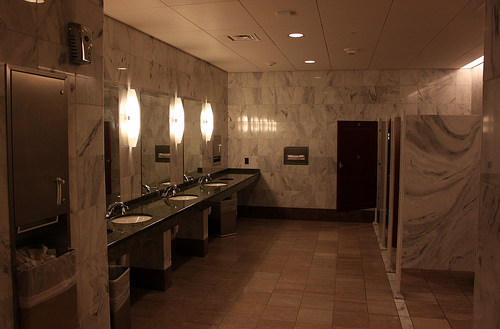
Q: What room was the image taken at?
A: It was taken at the bathroom.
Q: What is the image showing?
A: It is showing a bathroom.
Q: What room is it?
A: It is a bathroom.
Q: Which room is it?
A: It is a bathroom.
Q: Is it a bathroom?
A: Yes, it is a bathroom.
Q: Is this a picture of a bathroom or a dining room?
A: It is showing a bathroom.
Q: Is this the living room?
A: No, it is the bathroom.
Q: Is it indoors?
A: Yes, it is indoors.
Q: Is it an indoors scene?
A: Yes, it is indoors.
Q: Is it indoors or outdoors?
A: It is indoors.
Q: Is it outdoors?
A: No, it is indoors.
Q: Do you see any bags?
A: Yes, there is a bag.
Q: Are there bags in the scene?
A: Yes, there is a bag.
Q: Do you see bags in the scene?
A: Yes, there is a bag.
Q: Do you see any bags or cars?
A: Yes, there is a bag.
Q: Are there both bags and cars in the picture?
A: No, there is a bag but no cars.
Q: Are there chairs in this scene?
A: No, there are no chairs.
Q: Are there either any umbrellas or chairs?
A: No, there are no chairs or umbrellas.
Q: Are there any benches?
A: No, there are no benches.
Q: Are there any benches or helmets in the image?
A: No, there are no benches or helmets.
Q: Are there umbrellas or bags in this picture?
A: Yes, there is a bag.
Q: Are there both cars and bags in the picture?
A: No, there is a bag but no cars.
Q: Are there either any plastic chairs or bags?
A: Yes, there is a plastic bag.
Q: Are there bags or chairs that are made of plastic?
A: Yes, the bag is made of plastic.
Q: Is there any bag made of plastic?
A: Yes, there is a bag that is made of plastic.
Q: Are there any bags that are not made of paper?
A: Yes, there is a bag that is made of plastic.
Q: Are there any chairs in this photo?
A: No, there are no chairs.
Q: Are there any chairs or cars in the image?
A: No, there are no chairs or cars.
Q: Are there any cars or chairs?
A: No, there are no chairs or cars.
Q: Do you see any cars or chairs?
A: No, there are no chairs or cars.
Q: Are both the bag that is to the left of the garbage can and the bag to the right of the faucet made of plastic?
A: Yes, both the bag and the bag are made of plastic.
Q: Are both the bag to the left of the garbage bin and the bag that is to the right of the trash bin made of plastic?
A: Yes, both the bag and the bag are made of plastic.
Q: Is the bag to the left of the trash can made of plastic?
A: Yes, the bag is made of plastic.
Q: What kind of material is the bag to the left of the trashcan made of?
A: The bag is made of plastic.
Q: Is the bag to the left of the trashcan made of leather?
A: No, the bag is made of plastic.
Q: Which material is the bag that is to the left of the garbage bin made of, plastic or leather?
A: The bag is made of plastic.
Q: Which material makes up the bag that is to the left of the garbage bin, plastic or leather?
A: The bag is made of plastic.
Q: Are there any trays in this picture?
A: No, there are no trays.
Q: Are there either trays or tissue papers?
A: No, there are no trays or tissue papers.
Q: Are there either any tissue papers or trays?
A: No, there are no trays or tissue papers.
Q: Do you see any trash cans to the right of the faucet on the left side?
A: Yes, there is a trash can to the right of the faucet.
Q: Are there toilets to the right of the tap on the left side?
A: No, there is a trash can to the right of the tap.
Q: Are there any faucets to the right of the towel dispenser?
A: Yes, there is a faucet to the right of the towel dispenser.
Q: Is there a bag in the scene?
A: Yes, there is a bag.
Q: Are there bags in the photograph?
A: Yes, there is a bag.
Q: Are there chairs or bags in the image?
A: Yes, there is a bag.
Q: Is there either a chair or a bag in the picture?
A: Yes, there is a bag.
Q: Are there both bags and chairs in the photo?
A: No, there is a bag but no chairs.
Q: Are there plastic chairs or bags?
A: Yes, there is a plastic bag.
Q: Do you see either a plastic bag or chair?
A: Yes, there is a plastic bag.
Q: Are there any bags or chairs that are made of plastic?
A: Yes, the bag is made of plastic.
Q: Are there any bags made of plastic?
A: Yes, there is a bag that is made of plastic.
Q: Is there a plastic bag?
A: Yes, there is a bag that is made of plastic.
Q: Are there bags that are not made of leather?
A: Yes, there is a bag that is made of plastic.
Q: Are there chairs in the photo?
A: No, there are no chairs.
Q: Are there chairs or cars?
A: No, there are no chairs or cars.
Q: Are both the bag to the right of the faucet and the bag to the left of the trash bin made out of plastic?
A: Yes, both the bag and the bag are made of plastic.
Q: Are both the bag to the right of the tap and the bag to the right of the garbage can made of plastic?
A: Yes, both the bag and the bag are made of plastic.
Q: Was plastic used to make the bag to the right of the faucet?
A: Yes, the bag is made of plastic.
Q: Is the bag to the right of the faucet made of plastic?
A: Yes, the bag is made of plastic.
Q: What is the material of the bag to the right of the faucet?
A: The bag is made of plastic.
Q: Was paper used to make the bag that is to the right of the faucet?
A: No, the bag is made of plastic.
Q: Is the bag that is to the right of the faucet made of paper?
A: No, the bag is made of plastic.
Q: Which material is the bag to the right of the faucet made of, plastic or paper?
A: The bag is made of plastic.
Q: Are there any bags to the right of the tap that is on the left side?
A: Yes, there is a bag to the right of the faucet.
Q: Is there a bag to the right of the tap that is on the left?
A: Yes, there is a bag to the right of the faucet.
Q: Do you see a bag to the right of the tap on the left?
A: Yes, there is a bag to the right of the faucet.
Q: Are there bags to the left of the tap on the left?
A: No, the bag is to the right of the tap.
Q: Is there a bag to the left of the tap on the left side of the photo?
A: No, the bag is to the right of the tap.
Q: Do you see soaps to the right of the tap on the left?
A: No, there is a bag to the right of the faucet.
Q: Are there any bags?
A: Yes, there is a bag.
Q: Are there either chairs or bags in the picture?
A: Yes, there is a bag.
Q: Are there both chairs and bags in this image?
A: No, there is a bag but no chairs.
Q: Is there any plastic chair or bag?
A: Yes, there is a plastic bag.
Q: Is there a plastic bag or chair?
A: Yes, there is a plastic bag.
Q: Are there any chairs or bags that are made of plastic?
A: Yes, the bag is made of plastic.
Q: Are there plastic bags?
A: Yes, there is a bag that is made of plastic.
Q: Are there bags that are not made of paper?
A: Yes, there is a bag that is made of plastic.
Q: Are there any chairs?
A: No, there are no chairs.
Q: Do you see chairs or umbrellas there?
A: No, there are no chairs or umbrellas.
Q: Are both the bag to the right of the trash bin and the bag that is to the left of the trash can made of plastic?
A: Yes, both the bag and the bag are made of plastic.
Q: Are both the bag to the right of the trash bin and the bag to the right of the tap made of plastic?
A: Yes, both the bag and the bag are made of plastic.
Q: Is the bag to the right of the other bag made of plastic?
A: Yes, the bag is made of plastic.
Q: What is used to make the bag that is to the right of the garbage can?
A: The bag is made of plastic.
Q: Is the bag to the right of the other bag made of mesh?
A: No, the bag is made of plastic.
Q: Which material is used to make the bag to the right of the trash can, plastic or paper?
A: The bag is made of plastic.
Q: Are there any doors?
A: Yes, there is a door.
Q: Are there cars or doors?
A: Yes, there is a door.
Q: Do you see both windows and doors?
A: No, there is a door but no windows.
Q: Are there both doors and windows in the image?
A: No, there is a door but no windows.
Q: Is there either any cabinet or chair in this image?
A: No, there are no chairs or cabinets.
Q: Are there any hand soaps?
A: No, there are no hand soaps.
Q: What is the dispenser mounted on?
A: The dispenser is mounted on the wall.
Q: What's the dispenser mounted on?
A: The dispenser is mounted on the wall.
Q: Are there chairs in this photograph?
A: No, there are no chairs.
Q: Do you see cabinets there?
A: No, there are no cabinets.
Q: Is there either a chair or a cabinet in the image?
A: No, there are no cabinets or chairs.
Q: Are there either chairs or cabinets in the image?
A: No, there are no cabinets or chairs.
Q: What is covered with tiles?
A: The floor is covered with tiles.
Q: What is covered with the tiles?
A: The floor is covered with tiles.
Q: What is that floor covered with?
A: The floor is covered with tiles.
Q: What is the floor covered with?
A: The floor is covered with tiles.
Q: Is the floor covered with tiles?
A: Yes, the floor is covered with tiles.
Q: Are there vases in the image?
A: No, there are no vases.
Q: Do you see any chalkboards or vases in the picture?
A: No, there are no vases or chalkboards.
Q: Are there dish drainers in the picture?
A: No, there are no dish drainers.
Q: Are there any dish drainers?
A: No, there are no dish drainers.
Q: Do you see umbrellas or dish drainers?
A: No, there are no dish drainers or umbrellas.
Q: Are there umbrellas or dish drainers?
A: No, there are no dish drainers or umbrellas.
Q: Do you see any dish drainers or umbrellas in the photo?
A: No, there are no dish drainers or umbrellas.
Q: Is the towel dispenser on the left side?
A: Yes, the towel dispenser is on the left of the image.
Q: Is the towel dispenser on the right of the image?
A: No, the towel dispenser is on the left of the image.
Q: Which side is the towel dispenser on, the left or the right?
A: The towel dispenser is on the left of the image.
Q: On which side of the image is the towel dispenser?
A: The towel dispenser is on the left of the image.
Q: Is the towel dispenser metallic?
A: Yes, the towel dispenser is metallic.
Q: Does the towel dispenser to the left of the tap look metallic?
A: Yes, the towel dispenser is metallic.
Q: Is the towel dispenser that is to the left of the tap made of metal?
A: Yes, the towel dispenser is made of metal.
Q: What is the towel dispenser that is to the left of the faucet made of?
A: The towel dispenser is made of metal.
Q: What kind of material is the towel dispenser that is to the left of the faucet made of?
A: The towel dispenser is made of metal.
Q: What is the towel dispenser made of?
A: The towel dispenser is made of metal.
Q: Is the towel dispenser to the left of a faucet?
A: Yes, the towel dispenser is to the left of a faucet.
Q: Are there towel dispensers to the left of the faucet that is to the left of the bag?
A: Yes, there is a towel dispenser to the left of the faucet.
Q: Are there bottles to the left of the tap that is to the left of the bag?
A: No, there is a towel dispenser to the left of the tap.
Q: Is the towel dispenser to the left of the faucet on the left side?
A: Yes, the towel dispenser is to the left of the faucet.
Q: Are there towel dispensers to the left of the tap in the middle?
A: Yes, there is a towel dispenser to the left of the tap.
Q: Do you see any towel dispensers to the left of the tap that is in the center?
A: Yes, there is a towel dispenser to the left of the tap.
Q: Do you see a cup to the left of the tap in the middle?
A: No, there is a towel dispenser to the left of the tap.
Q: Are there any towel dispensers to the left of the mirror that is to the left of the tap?
A: Yes, there is a towel dispenser to the left of the mirror.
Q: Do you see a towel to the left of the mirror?
A: No, there is a towel dispenser to the left of the mirror.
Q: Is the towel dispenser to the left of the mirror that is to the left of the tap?
A: Yes, the towel dispenser is to the left of the mirror.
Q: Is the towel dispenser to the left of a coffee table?
A: No, the towel dispenser is to the left of the mirror.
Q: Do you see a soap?
A: No, there are no soaps.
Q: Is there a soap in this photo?
A: No, there are no soaps.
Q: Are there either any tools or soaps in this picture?
A: No, there are no soaps or tools.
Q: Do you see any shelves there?
A: No, there are no shelves.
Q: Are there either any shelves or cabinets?
A: No, there are no shelves or cabinets.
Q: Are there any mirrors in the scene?
A: Yes, there is a mirror.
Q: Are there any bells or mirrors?
A: Yes, there is a mirror.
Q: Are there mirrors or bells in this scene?
A: Yes, there is a mirror.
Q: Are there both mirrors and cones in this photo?
A: No, there is a mirror but no cones.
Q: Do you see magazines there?
A: No, there are no magazines.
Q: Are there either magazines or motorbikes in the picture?
A: No, there are no magazines or motorbikes.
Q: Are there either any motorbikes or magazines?
A: No, there are no magazines or motorbikes.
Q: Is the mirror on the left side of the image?
A: Yes, the mirror is on the left of the image.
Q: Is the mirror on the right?
A: No, the mirror is on the left of the image.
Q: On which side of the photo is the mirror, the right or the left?
A: The mirror is on the left of the image.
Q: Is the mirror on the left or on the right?
A: The mirror is on the left of the image.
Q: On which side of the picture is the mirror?
A: The mirror is on the left of the image.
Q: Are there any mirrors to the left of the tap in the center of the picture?
A: Yes, there is a mirror to the left of the tap.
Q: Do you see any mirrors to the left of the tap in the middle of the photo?
A: Yes, there is a mirror to the left of the tap.